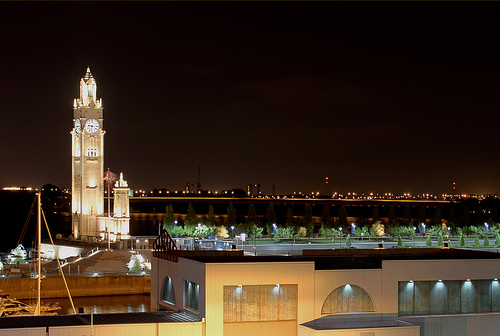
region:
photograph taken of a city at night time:
[6, 35, 484, 327]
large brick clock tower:
[65, 60, 133, 235]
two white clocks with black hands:
[71, 114, 105, 142]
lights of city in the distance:
[35, 173, 484, 223]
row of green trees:
[168, 212, 493, 239]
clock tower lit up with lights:
[57, 60, 152, 236]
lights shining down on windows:
[392, 277, 498, 313]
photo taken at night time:
[18, 18, 477, 323]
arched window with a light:
[317, 275, 379, 318]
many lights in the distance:
[149, 173, 496, 199]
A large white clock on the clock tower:
[83, 115, 103, 135]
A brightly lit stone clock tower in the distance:
[66, 59, 134, 245]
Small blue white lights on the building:
[400, 277, 497, 309]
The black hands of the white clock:
[85, 122, 95, 129]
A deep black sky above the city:
[121, 8, 488, 162]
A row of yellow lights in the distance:
[155, 186, 490, 209]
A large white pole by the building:
[21, 187, 86, 313]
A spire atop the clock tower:
[80, 64, 97, 86]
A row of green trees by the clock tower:
[161, 200, 495, 236]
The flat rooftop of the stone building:
[173, 243, 489, 273]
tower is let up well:
[70, 66, 132, 246]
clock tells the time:
[85, 116, 100, 135]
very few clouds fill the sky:
[1, 1, 491, 195]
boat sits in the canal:
[1, 191, 78, 316]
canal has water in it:
[0, 278, 150, 313]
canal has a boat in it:
[0, 192, 153, 313]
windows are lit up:
[159, 272, 499, 315]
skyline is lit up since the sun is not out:
[128, 175, 498, 202]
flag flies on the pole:
[101, 166, 116, 218]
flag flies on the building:
[102, 169, 114, 215]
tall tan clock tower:
[62, 58, 132, 242]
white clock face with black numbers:
[80, 112, 99, 137]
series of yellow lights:
[0, 171, 499, 208]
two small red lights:
[321, 172, 331, 186]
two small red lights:
[449, 178, 458, 190]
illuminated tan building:
[7, 238, 499, 334]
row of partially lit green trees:
[150, 195, 498, 253]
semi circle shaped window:
[316, 276, 376, 318]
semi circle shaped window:
[155, 268, 178, 307]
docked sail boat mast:
[0, 186, 81, 316]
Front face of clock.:
[83, 115, 99, 134]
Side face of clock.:
[70, 114, 82, 135]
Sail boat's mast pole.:
[28, 185, 48, 317]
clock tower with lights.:
[67, 60, 105, 236]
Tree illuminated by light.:
[156, 200, 180, 237]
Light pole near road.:
[337, 224, 344, 250]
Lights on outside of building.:
[229, 281, 287, 298]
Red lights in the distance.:
[321, 173, 331, 198]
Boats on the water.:
[2, 291, 65, 318]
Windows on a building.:
[222, 281, 300, 323]